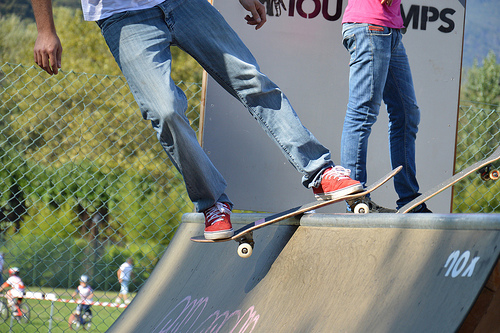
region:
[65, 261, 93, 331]
Small child in the grass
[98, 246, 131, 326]
Small child in the grass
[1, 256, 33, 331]
Small child in the grass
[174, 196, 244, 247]
Red and white shoe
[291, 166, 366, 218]
Red and white shoe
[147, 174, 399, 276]
Black and white skateboard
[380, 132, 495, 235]
Black and white skateboard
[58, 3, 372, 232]
Pair of denim jeans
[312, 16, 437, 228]
Pair of denim jeans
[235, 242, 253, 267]
White and black wheel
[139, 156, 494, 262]
The boy is wearing red shoes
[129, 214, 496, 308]
writing is on the skateboard ramp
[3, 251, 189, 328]
children are riding bikes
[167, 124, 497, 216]
a boy is riding a skateboard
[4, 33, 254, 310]
Trees are behind the fence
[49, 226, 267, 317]
A man is walking on the grass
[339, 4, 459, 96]
A girl is wearing a pink shirt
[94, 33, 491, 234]
Both people are wearing jeans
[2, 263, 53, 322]
The kid is wearing a helmet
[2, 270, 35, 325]
The boy is wearing red and white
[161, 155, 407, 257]
Skateboard grinding on rail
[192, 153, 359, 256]
Red shoes of skateboarder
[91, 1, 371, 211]
Legs of skateboarder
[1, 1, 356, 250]
Guy performing a skating trick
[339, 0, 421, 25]
Pink shirt worn by skater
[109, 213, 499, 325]
Black skating ramp with graffiti on it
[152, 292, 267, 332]
Pink graffiti letters on skate ramp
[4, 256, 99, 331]
Little kids riding bikes in park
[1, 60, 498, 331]
A large metal fence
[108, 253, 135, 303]
Man in a white shirt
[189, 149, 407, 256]
a skateboard flying through the air.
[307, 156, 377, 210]
a red left shoe.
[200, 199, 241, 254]
a red right shoe.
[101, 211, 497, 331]
a large skateboard ramp.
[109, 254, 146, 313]
a woman walking near a fence.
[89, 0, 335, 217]
A pair of blue jeans.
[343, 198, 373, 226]
a white skateboard wheel.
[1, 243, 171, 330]
a fence in a field.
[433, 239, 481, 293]
writing on a skateboard ramp.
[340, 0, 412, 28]
a pink t shirt.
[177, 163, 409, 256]
Black skateboard on the ramp.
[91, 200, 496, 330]
Skateboard ramp in the forefront.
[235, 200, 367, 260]
White wheels on the skateboard.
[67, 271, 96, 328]
Child riding a bike.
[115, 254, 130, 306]
Person walking in the background.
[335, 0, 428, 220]
Pink shirt on the person.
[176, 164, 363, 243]
Red shoes on the feet.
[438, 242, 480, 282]
White writing on the ramp.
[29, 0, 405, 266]
Person skating on the ramp.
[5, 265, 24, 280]
Helmet on the child.